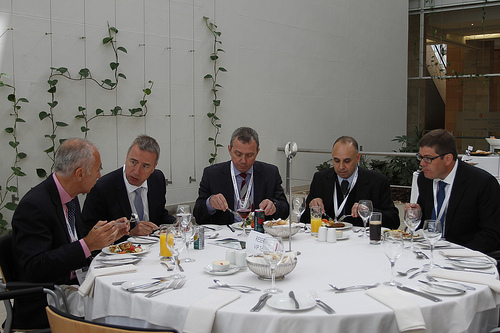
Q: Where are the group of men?
A: Around a table.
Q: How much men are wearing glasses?
A: One.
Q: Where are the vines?
A: On the wall.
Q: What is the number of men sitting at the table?
A: Five.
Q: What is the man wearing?
A: A gray tie.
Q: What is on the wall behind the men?
A: A green vine.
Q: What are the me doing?
A: Eating dinner.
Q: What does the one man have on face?
A: Glasses.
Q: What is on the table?
A: A tablecloth.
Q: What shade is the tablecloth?
A: White.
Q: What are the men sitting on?
A: Chairs.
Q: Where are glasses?
A: On the table.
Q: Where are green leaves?
A: On the wall.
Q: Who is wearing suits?
A: Five men.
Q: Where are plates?
A: On the table.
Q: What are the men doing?
A: Eating.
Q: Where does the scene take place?
A: At a restaurant.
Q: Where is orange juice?
A: In glasses.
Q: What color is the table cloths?
A: White.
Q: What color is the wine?
A: Red.